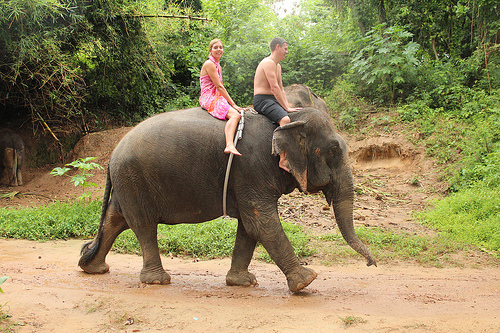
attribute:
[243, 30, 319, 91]
man — shirtless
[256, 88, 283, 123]
shorts — black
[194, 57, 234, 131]
dress — pink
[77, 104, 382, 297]
elephant — large, grey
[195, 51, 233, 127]
dress — pink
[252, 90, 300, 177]
shorts — black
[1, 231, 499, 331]
path — dirt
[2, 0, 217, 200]
trees — thick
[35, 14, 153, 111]
leaves — green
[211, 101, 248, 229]
harness — brown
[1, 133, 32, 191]
stump — brown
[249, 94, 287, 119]
shorts — black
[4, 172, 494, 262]
grass — green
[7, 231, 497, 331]
dirt — brown 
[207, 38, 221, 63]
hair — blonde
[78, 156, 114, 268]
tail — black